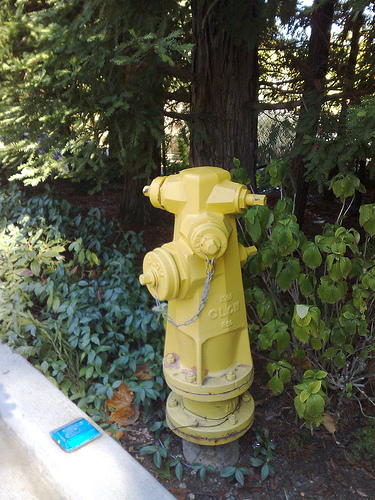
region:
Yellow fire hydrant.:
[134, 162, 269, 448]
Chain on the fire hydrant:
[150, 258, 218, 326]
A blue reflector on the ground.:
[41, 415, 105, 458]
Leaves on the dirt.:
[297, 440, 370, 498]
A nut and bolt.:
[227, 410, 239, 428]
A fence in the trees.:
[261, 116, 301, 147]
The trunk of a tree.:
[193, 5, 257, 190]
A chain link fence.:
[255, 111, 295, 167]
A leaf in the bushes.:
[97, 375, 146, 436]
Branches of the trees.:
[261, 79, 304, 114]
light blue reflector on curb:
[52, 410, 112, 457]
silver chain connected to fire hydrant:
[143, 241, 224, 330]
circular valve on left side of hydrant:
[142, 168, 170, 213]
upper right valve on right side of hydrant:
[236, 187, 278, 228]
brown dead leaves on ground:
[79, 369, 157, 434]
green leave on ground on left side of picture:
[16, 282, 123, 352]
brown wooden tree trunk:
[201, 42, 255, 143]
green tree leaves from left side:
[28, 35, 118, 125]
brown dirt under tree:
[75, 194, 122, 220]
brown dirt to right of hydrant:
[285, 409, 362, 497]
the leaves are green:
[303, 394, 313, 406]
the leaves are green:
[300, 392, 313, 412]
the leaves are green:
[306, 397, 315, 415]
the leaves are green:
[308, 394, 318, 418]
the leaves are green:
[303, 388, 309, 419]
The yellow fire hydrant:
[133, 164, 273, 468]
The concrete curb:
[0, 338, 178, 498]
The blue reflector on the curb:
[47, 415, 103, 453]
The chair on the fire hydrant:
[153, 255, 216, 330]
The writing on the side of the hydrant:
[206, 284, 242, 331]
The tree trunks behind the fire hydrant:
[61, 1, 373, 227]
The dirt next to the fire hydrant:
[118, 375, 373, 498]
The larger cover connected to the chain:
[138, 248, 183, 306]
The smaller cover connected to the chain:
[190, 223, 228, 263]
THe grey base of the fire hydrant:
[179, 438, 243, 470]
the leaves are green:
[306, 400, 315, 409]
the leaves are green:
[303, 399, 312, 418]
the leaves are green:
[298, 394, 309, 408]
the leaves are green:
[305, 408, 316, 417]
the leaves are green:
[305, 404, 313, 413]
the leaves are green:
[301, 399, 306, 415]